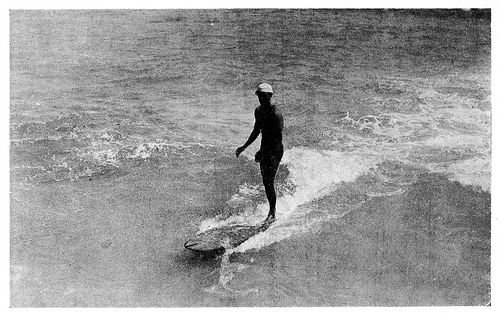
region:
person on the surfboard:
[157, 50, 321, 310]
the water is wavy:
[319, 115, 429, 242]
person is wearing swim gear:
[240, 137, 278, 201]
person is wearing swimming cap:
[248, 74, 278, 104]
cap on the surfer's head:
[242, 67, 304, 119]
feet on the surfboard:
[234, 171, 291, 256]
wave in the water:
[287, 128, 382, 248]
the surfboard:
[168, 197, 256, 264]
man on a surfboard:
[167, 70, 318, 268]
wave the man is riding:
[150, 135, 432, 258]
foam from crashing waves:
[305, 70, 485, 190]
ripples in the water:
[17, 15, 477, 110]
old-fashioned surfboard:
[172, 218, 270, 253]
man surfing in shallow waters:
[10, 77, 496, 287]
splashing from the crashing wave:
[15, 105, 180, 171]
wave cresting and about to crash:
[290, 152, 480, 210]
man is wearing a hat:
[250, 81, 281, 107]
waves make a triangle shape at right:
[220, 155, 491, 299]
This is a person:
[213, 67, 330, 267]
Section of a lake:
[326, 194, 493, 307]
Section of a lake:
[62, 21, 174, 121]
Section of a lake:
[317, 210, 479, 311]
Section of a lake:
[16, 197, 97, 307]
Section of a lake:
[343, 65, 494, 164]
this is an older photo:
[15, 22, 462, 301]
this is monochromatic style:
[47, 29, 445, 255]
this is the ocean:
[41, 101, 198, 266]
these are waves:
[287, 152, 485, 262]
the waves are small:
[332, 130, 482, 248]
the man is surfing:
[155, 29, 376, 269]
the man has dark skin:
[215, 88, 315, 218]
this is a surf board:
[173, 219, 279, 263]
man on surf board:
[232, 76, 285, 224]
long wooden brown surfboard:
[184, 219, 274, 255]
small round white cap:
[256, 82, 274, 95]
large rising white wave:
[236, 144, 498, 259]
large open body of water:
[12, 10, 494, 305]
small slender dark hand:
[232, 143, 244, 157]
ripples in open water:
[26, 106, 157, 185]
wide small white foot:
[260, 211, 279, 226]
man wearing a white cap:
[248, 75, 284, 102]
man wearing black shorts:
[251, 137, 283, 189]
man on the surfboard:
[153, 78, 298, 264]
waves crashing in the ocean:
[293, 125, 423, 209]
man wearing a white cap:
[248, 75, 279, 107]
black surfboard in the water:
[175, 200, 279, 269]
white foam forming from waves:
[284, 141, 356, 198]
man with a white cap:
[253, 79, 274, 91]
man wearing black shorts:
[246, 143, 289, 193]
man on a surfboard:
[173, 77, 311, 259]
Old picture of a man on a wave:
[181, 62, 329, 259]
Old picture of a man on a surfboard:
[181, 62, 298, 256]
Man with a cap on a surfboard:
[184, 80, 301, 257]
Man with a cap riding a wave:
[188, 80, 294, 263]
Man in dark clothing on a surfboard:
[184, 84, 289, 264]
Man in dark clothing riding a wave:
[183, 78, 285, 253]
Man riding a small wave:
[185, 83, 292, 258]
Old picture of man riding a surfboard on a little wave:
[188, 80, 305, 257]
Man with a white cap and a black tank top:
[181, 81, 293, 256]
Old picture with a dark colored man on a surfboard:
[184, 82, 293, 256]